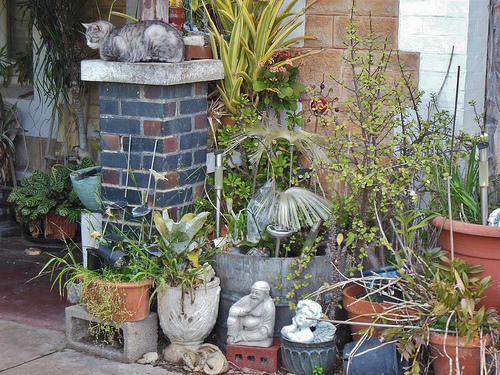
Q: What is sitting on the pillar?
A: A cat.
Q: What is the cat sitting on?
A: A pillar.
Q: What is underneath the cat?
A: A brick pedestal.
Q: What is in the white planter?
A: A green plant.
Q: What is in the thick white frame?
A: A window.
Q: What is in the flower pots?
A: Plants.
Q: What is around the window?
A: White frame.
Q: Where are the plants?
A: Vases.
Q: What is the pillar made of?
A: Brick.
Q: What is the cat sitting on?
A: Pillar.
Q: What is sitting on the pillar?
A: Cat.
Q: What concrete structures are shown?
A: Statues.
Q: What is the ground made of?
A: Concrete.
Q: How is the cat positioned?
A: Laying down.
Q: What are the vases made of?
A: Clay.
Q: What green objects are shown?
A: Plants.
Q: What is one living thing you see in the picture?
A: A cat.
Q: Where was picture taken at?
A: Someone's porch.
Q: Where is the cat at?
A: On a pedestal.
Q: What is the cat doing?
A: Lying down.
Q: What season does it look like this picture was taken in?
A: Summer.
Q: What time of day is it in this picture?
A: Daytime.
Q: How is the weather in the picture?
A: Maybe a bit overcast.